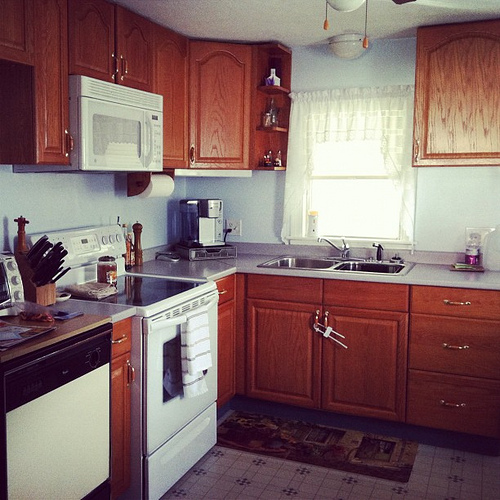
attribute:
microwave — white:
[15, 70, 163, 171]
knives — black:
[27, 237, 69, 283]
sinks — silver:
[264, 249, 407, 279]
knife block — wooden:
[15, 252, 58, 306]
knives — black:
[32, 233, 72, 292]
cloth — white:
[180, 305, 212, 400]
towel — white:
[189, 321, 218, 360]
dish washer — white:
[65, 227, 230, 498]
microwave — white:
[68, 61, 182, 179]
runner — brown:
[219, 409, 407, 474]